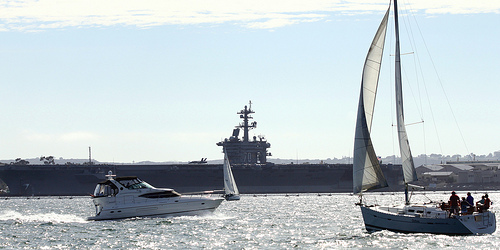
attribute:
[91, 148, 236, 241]
motorboat — large 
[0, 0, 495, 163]
sky — light blue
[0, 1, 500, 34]
clouds — thin